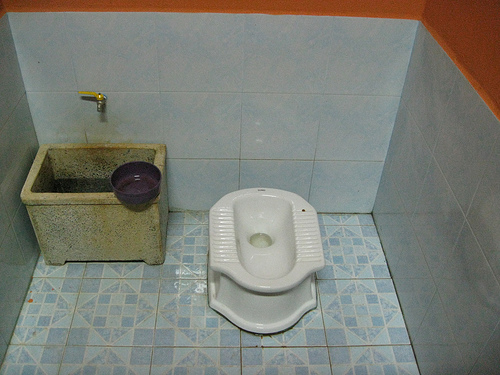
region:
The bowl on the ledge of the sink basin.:
[103, 152, 163, 205]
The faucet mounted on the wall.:
[80, 85, 110, 112]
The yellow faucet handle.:
[77, 87, 104, 97]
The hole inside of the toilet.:
[246, 230, 267, 250]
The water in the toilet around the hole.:
[245, 221, 270, 243]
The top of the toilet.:
[205, 185, 320, 285]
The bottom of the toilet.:
[195, 270, 325, 330]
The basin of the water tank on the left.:
[21, 130, 166, 266]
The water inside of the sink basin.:
[47, 161, 141, 198]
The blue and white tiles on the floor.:
[44, 183, 444, 374]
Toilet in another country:
[30, 56, 444, 349]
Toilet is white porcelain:
[196, 181, 337, 343]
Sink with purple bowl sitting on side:
[8, 54, 181, 277]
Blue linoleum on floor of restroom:
[100, 285, 252, 346]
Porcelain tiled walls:
[225, 54, 392, 189]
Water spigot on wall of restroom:
[58, 74, 118, 125]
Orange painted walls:
[387, 0, 497, 125]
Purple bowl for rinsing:
[100, 158, 175, 230]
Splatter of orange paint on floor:
[22, 282, 42, 314]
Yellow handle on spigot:
[76, 77, 118, 104]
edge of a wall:
[380, 268, 410, 318]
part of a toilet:
[229, 288, 254, 319]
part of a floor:
[247, 253, 269, 273]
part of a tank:
[23, 187, 38, 217]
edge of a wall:
[368, 182, 376, 198]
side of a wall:
[313, 118, 356, 185]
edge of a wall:
[193, 205, 205, 210]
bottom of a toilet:
[240, 311, 255, 347]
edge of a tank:
[124, 198, 138, 207]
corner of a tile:
[368, 161, 386, 206]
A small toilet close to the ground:
[201, 183, 353, 333]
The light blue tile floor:
[19, 320, 289, 374]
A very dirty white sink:
[22, 131, 184, 276]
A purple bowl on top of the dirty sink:
[99, 157, 169, 209]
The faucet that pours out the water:
[61, 83, 126, 115]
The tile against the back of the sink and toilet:
[159, 47, 414, 224]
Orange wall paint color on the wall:
[428, 38, 496, 120]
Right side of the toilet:
[287, 189, 334, 292]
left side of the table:
[206, 194, 244, 275]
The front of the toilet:
[204, 257, 326, 335]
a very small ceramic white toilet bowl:
[208, 178, 322, 332]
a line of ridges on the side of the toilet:
[211, 205, 239, 265]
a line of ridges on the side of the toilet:
[293, 203, 324, 268]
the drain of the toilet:
[252, 232, 273, 249]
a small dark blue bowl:
[114, 161, 159, 196]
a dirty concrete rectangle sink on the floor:
[27, 138, 174, 266]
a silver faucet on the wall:
[81, 86, 111, 110]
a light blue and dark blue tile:
[67, 274, 158, 346]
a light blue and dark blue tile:
[152, 277, 245, 350]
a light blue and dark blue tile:
[315, 276, 407, 350]